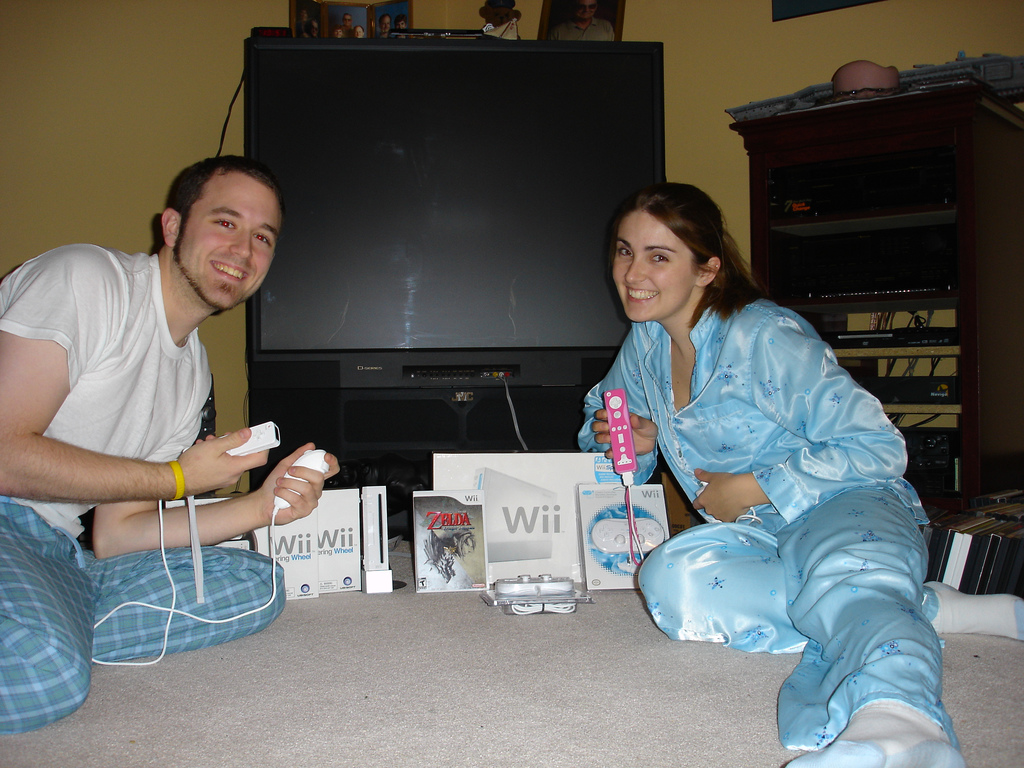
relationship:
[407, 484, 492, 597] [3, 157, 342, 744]
game near man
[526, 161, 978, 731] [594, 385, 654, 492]
woman holding remote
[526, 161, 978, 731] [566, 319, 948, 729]
woman wearing pajamas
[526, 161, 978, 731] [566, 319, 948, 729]
woman in pajamas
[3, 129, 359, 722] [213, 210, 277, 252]
man has eyes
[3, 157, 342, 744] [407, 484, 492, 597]
man near game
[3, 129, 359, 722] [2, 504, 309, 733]
man wearing pants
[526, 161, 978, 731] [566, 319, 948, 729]
woman in blue pajamas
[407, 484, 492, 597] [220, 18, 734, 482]
game near tv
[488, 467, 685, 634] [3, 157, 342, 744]
controllers near man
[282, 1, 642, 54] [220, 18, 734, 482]
pictures on tv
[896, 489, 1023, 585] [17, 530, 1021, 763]
books on floor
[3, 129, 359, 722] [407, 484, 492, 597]
man near game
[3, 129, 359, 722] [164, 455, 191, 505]
man wearing bracelet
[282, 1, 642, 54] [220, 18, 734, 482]
pictures on top of tv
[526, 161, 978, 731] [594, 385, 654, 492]
woman holding wii remote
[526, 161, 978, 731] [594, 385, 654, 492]
woman holding pink remote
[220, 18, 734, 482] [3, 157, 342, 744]
tv behind man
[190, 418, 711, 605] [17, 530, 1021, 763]
boxes on floor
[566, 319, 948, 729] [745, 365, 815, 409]
pajamas are light blue